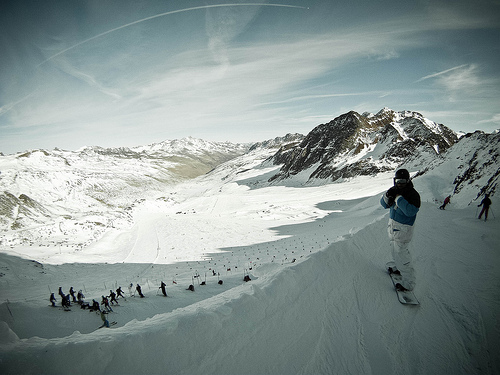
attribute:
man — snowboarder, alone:
[381, 168, 425, 290]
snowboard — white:
[385, 260, 419, 307]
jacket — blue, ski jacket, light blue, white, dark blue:
[381, 184, 420, 226]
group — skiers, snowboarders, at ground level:
[49, 280, 173, 328]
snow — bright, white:
[1, 174, 500, 374]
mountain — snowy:
[2, 135, 254, 229]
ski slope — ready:
[0, 171, 412, 339]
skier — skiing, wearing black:
[473, 192, 495, 220]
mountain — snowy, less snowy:
[197, 105, 467, 190]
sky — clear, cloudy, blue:
[0, 0, 498, 154]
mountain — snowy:
[404, 131, 499, 210]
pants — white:
[389, 220, 417, 291]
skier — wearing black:
[439, 194, 454, 211]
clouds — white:
[0, 13, 499, 150]